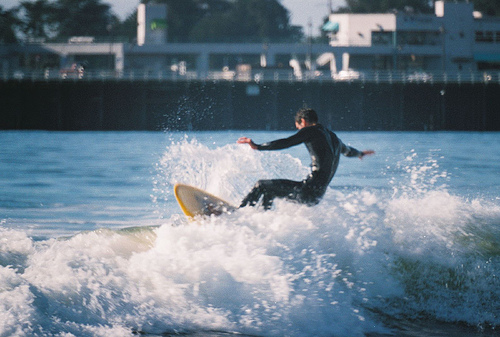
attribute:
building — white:
[317, 8, 484, 84]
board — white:
[172, 178, 222, 221]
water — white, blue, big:
[14, 142, 439, 329]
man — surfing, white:
[177, 89, 371, 227]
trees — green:
[13, 2, 294, 58]